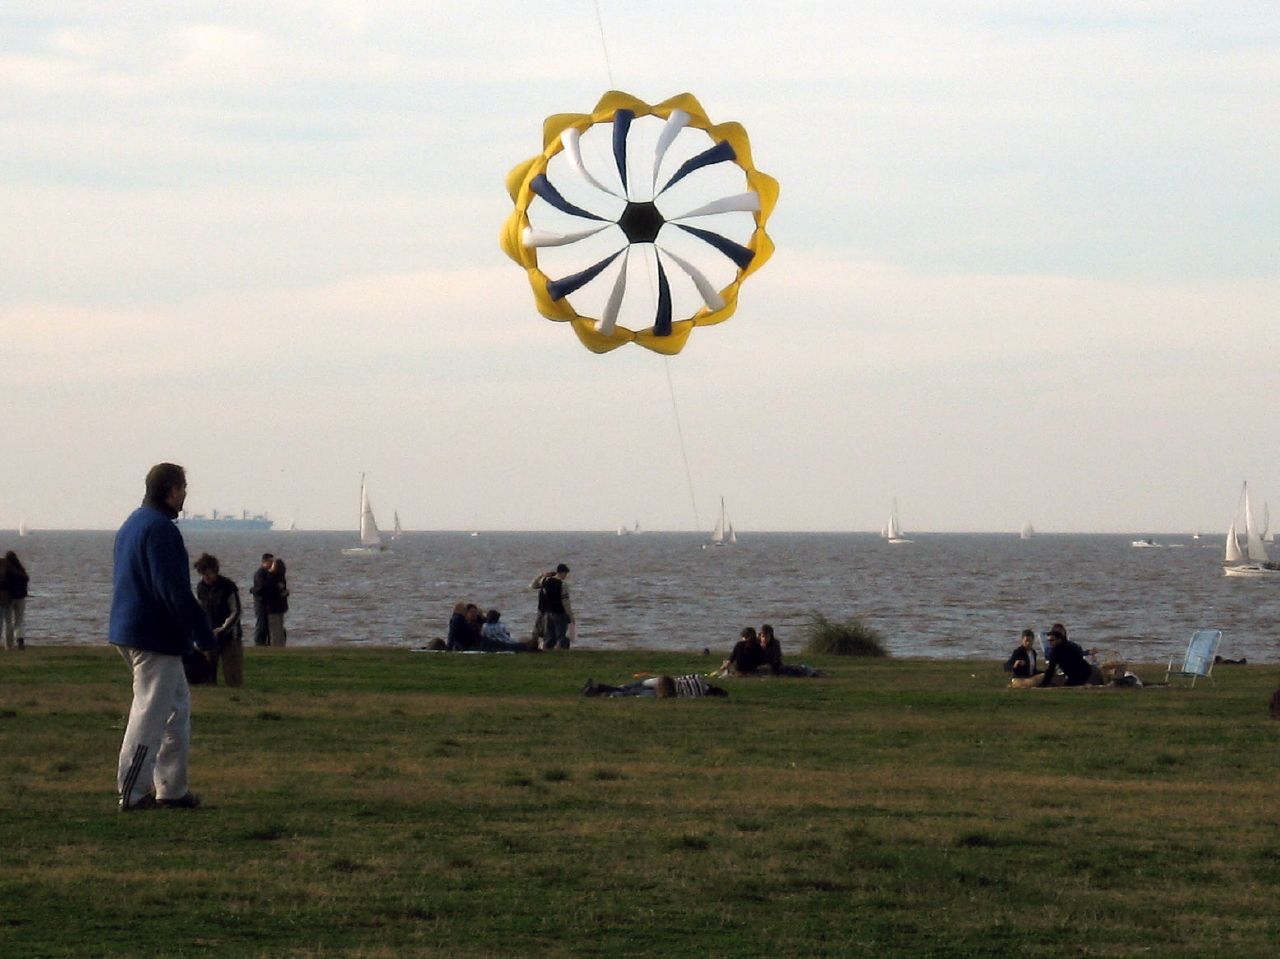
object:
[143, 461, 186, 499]
hair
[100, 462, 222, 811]
man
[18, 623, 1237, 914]
field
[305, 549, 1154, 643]
water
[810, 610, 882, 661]
bush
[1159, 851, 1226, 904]
grass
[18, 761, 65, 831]
grass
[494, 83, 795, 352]
border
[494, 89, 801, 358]
kite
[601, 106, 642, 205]
blades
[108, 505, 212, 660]
coat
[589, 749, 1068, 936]
ground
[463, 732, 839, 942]
view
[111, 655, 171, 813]
legs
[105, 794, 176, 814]
shoes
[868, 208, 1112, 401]
clouds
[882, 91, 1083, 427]
view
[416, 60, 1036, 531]
view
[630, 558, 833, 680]
water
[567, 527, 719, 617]
view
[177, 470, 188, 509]
face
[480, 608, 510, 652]
people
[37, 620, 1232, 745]
shore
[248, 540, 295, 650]
couple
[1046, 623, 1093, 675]
woman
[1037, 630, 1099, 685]
chair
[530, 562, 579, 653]
couple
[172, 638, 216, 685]
bag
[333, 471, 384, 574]
boat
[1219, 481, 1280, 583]
boat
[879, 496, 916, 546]
boat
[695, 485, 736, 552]
boat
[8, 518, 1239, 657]
water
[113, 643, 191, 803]
pants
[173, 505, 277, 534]
ship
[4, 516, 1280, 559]
horizon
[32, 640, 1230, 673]
shoreline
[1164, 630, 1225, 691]
chair